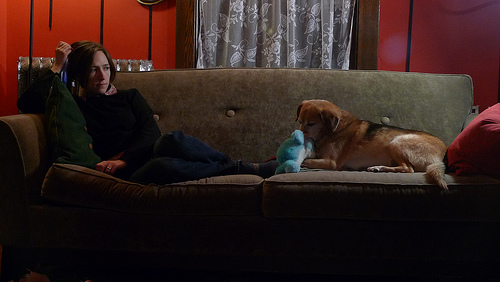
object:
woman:
[17, 39, 281, 183]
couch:
[1, 68, 499, 264]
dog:
[295, 98, 450, 192]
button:
[225, 109, 237, 117]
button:
[151, 113, 160, 121]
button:
[379, 116, 391, 125]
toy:
[270, 129, 314, 174]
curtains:
[193, 0, 356, 70]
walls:
[1, 0, 499, 117]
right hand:
[50, 41, 72, 67]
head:
[67, 40, 118, 94]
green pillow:
[43, 74, 102, 169]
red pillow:
[444, 101, 498, 176]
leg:
[300, 138, 347, 170]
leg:
[365, 141, 415, 174]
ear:
[321, 108, 341, 134]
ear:
[294, 101, 304, 123]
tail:
[425, 153, 449, 192]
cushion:
[39, 162, 264, 216]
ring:
[106, 166, 112, 169]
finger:
[103, 163, 114, 174]